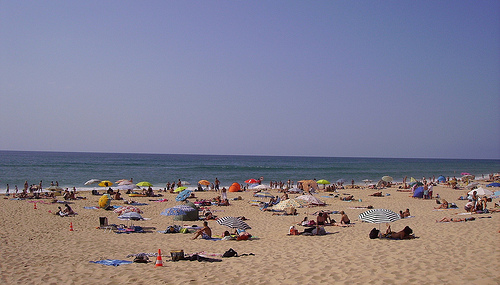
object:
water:
[0, 149, 500, 195]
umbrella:
[199, 179, 212, 187]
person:
[297, 216, 317, 227]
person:
[340, 211, 351, 224]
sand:
[406, 258, 498, 284]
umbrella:
[359, 208, 401, 232]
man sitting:
[99, 193, 114, 210]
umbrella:
[244, 178, 258, 184]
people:
[189, 221, 212, 240]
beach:
[2, 169, 498, 284]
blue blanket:
[91, 257, 131, 267]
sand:
[0, 243, 75, 281]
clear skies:
[0, 1, 500, 159]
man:
[412, 181, 423, 200]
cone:
[154, 248, 163, 267]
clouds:
[2, 78, 329, 153]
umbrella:
[136, 181, 154, 189]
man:
[382, 222, 416, 240]